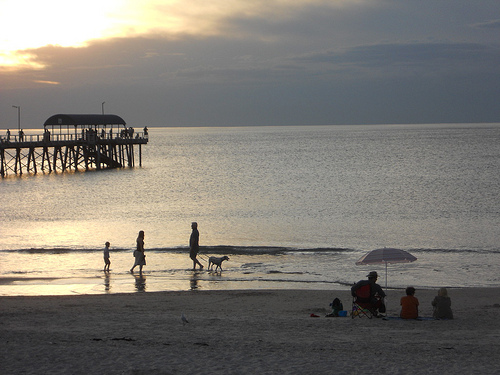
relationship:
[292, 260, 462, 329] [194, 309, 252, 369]
people enjoying beach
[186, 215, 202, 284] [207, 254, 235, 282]
man walking dog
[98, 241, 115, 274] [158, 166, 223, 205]
small child walking in water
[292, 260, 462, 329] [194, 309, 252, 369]
people on beach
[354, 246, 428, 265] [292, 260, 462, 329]
umbrella over people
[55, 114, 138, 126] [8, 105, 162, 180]
roof over pier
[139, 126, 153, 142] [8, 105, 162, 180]
man on pier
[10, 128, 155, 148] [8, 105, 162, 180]
people on pier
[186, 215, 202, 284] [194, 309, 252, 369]
man on beach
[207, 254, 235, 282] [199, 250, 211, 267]
dog on leash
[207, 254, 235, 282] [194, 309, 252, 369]
dog on beach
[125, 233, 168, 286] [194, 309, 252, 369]
woman on beach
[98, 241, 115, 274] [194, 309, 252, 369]
small child on beach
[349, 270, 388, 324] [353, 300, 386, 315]
man sitting on chair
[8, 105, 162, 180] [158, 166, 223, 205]
pier over water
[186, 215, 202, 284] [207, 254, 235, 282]
man with dog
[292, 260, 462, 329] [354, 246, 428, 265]
people under umbrella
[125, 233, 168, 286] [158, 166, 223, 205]
woman in water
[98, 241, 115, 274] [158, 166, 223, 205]
small child in water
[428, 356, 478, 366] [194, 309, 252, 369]
sand on beach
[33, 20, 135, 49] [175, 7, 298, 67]
sun behind clouds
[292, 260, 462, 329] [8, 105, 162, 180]
people on pier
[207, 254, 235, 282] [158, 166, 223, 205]
dog in water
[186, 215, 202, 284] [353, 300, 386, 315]
man sitting on chair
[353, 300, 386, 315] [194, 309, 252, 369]
chair on beach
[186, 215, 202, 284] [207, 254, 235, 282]
man and dog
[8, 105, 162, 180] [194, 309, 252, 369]
pier on beach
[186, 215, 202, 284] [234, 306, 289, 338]
man sitting on beach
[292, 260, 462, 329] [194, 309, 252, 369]
people sitting on beach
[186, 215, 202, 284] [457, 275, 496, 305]
man on shore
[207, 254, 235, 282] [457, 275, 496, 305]
dog on shore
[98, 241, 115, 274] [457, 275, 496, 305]
small child walking on shore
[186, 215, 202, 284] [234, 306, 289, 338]
man walking on on beach